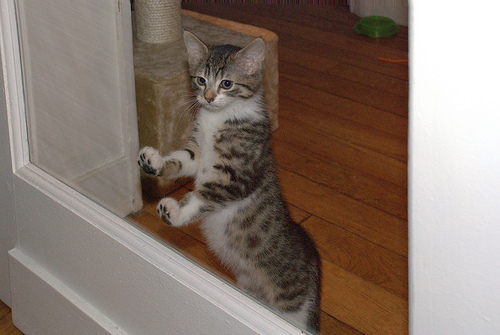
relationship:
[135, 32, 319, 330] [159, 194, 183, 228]
cat has left paw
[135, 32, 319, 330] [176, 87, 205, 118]
cat has whiskers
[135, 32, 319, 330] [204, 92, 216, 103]
cat has nose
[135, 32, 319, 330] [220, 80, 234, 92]
cat has left eye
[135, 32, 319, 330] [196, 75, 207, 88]
cat has right eye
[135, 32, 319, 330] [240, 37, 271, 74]
cat has left ear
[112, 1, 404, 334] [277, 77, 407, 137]
floor has slat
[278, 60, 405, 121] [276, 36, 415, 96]
slat next to slat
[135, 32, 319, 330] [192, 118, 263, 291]
cat has underbelly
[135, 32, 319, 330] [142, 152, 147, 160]
cat has pad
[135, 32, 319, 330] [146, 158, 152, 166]
cat has pad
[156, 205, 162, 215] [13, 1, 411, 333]
pad on glass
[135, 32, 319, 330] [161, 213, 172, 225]
cat has pad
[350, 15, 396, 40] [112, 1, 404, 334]
bowl on top of floor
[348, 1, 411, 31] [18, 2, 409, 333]
wall inside room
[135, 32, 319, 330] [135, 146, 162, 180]
cat has right paw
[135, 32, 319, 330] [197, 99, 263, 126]
cat has neck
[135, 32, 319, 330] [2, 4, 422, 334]
cat standing against door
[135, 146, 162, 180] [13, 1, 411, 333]
right paw flat against glass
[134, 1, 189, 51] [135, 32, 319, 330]
scratching pad for cat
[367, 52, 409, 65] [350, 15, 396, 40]
object by bowl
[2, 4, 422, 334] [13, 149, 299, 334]
door has base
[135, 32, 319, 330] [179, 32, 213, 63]
cat has right ear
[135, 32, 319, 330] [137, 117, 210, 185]
cat has front leg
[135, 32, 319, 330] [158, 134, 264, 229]
cat has front leg